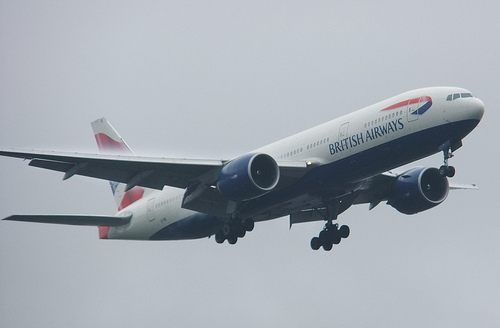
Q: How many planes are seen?
A: One.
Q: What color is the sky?
A: Gray.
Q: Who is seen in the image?
A: Nobody.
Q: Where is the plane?
A: In the sky.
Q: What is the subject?
A: An airplane.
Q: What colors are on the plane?
A: White, blue, and red.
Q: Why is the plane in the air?
A: It's traveling.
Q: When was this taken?
A: During the day.